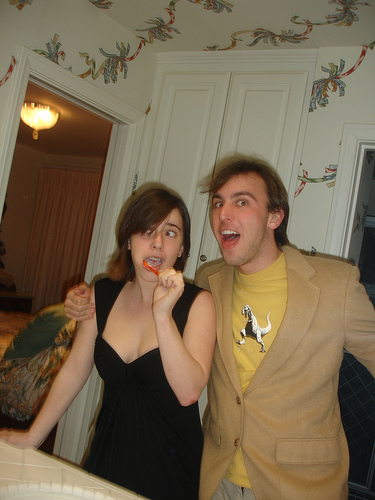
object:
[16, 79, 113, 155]
ceiling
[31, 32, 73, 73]
graphics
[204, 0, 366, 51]
graphics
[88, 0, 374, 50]
ceiling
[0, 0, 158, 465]
wall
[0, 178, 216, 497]
woman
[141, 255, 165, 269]
mouth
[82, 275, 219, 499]
dress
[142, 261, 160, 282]
toothbrush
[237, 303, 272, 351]
dinosaur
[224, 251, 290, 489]
shirt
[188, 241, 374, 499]
suit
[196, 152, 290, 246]
hair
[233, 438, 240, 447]
button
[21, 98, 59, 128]
light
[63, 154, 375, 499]
man